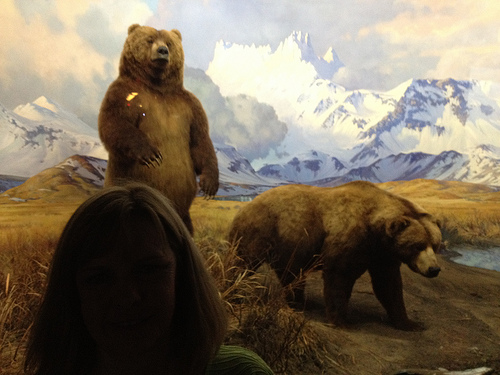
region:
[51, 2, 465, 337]
these are not real bears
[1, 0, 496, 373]
a museum exhibit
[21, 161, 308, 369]
a woman is posing for a photograph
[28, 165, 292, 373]
it is dark so her face is enveloped by shadows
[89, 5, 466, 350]
large bear statues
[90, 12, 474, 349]
life like bear statues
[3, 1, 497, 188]
a mural of a snowy mountain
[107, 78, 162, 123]
a reflection of light on the glass window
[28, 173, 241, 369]
she has shoulder-length brown hair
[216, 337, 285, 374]
she is wearing a green shirt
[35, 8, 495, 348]
Bears in a museum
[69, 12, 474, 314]
two bears in a museum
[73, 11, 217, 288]
A stuffed bear standing up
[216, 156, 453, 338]
A stuffed bear on all fours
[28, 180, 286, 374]
a woman in front of two bears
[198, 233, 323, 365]
Grass behind a woman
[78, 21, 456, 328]
Two bears on display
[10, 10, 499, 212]
Scenery behind the bears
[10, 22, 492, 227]
Mountains behind the bears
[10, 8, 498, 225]
Mountains painted behind the bears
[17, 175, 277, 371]
Woman in green shirt posing for a picture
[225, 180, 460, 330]
Bear walking away in background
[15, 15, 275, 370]
Bear standing up behind woman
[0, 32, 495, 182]
Snowy mountains in distance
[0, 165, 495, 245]
Brown grass in background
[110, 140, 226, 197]
Long sharp claws on bear's paw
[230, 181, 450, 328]
Bear looking at the ground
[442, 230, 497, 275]
Water in the background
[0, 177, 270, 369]
Woman standing in front of tall grass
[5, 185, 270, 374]
Woman in green shirt standing and smiling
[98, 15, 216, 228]
a brown bear on it's hind legs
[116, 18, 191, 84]
the head of a brown bear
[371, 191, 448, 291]
the head of a brown bear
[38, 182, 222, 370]
the head of a person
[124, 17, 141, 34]
the ear of a bear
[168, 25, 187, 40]
the head of a brown bear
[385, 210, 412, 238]
the head of a brown bear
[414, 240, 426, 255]
the eye of a bear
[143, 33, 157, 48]
the eye of a bear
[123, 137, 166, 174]
the paw of a bear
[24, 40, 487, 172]
The mountains are snow covered.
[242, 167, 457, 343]
The bear is on all four legs.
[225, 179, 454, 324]
The bear is brown.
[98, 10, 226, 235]
The bear is standing up.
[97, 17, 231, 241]
The bear is brown.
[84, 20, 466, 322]
two bears together.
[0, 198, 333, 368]
The grass is dead.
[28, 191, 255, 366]
The is smiling.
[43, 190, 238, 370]
There is a shadow on her face.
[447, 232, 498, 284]
The pond is by the hill.